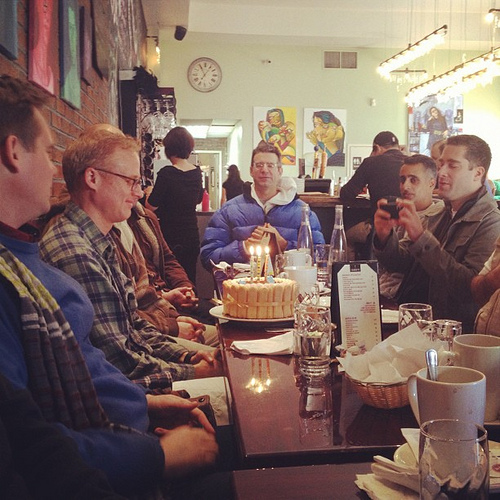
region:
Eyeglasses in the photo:
[95, 167, 152, 193]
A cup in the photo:
[405, 367, 492, 434]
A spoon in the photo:
[419, 350, 443, 387]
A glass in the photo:
[412, 414, 492, 495]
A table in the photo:
[252, 402, 297, 462]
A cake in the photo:
[214, 271, 300, 319]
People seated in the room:
[0, 109, 158, 452]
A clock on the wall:
[173, 52, 233, 97]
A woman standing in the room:
[148, 119, 203, 249]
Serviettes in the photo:
[340, 344, 406, 379]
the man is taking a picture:
[368, 133, 493, 223]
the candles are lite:
[247, 240, 274, 268]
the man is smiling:
[104, 150, 143, 221]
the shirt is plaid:
[66, 244, 98, 271]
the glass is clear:
[303, 314, 325, 338]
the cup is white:
[443, 388, 473, 408]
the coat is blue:
[230, 204, 255, 221]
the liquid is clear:
[306, 343, 326, 360]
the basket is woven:
[364, 375, 402, 410]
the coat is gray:
[458, 227, 480, 262]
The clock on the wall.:
[184, 53, 226, 96]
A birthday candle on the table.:
[210, 237, 297, 330]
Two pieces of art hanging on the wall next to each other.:
[250, 103, 349, 165]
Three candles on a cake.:
[245, 240, 276, 282]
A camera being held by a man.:
[373, 188, 416, 230]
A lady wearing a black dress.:
[148, 125, 208, 298]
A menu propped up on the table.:
[326, 252, 392, 365]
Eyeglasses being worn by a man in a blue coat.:
[252, 158, 281, 175]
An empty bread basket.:
[337, 318, 445, 407]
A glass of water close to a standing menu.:
[290, 299, 334, 381]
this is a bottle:
[296, 207, 316, 245]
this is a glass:
[420, 424, 462, 496]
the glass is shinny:
[430, 436, 469, 495]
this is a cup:
[413, 372, 482, 408]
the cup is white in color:
[432, 390, 474, 411]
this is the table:
[240, 407, 276, 458]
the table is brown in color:
[245, 385, 275, 444]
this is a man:
[79, 142, 162, 304]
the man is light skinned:
[97, 180, 125, 214]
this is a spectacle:
[121, 165, 151, 187]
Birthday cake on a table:
[206, 240, 301, 325]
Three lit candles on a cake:
[245, 243, 271, 281]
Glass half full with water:
[295, 305, 332, 378]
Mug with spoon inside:
[407, 347, 490, 484]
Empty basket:
[340, 326, 450, 409]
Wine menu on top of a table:
[330, 258, 387, 364]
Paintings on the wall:
[251, 104, 346, 168]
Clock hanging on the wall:
[182, 55, 224, 97]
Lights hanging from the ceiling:
[374, 9, 498, 107]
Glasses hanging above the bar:
[132, 85, 174, 138]